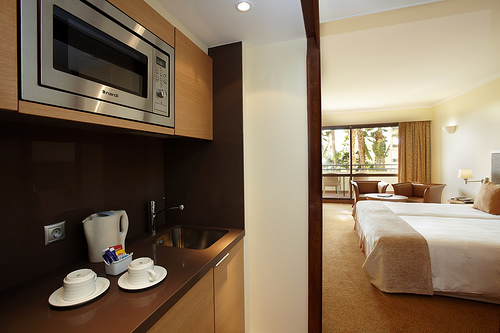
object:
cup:
[128, 256, 154, 284]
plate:
[116, 263, 167, 290]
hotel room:
[5, 2, 497, 331]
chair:
[390, 182, 439, 201]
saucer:
[47, 275, 111, 307]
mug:
[62, 266, 99, 302]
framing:
[306, 20, 328, 333]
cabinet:
[173, 35, 213, 141]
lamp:
[459, 169, 490, 186]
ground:
[404, 163, 430, 185]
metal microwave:
[19, 2, 177, 130]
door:
[38, 6, 151, 111]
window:
[319, 129, 410, 178]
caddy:
[102, 246, 137, 277]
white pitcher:
[81, 209, 129, 263]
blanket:
[356, 198, 494, 290]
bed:
[353, 198, 499, 303]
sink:
[150, 225, 231, 250]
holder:
[101, 244, 133, 276]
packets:
[101, 244, 126, 263]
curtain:
[396, 120, 430, 186]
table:
[366, 192, 406, 201]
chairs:
[351, 180, 389, 206]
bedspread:
[388, 201, 498, 298]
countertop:
[0, 225, 246, 332]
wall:
[252, 33, 339, 331]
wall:
[414, 122, 499, 218]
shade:
[432, 154, 474, 204]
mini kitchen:
[1, 0, 277, 330]